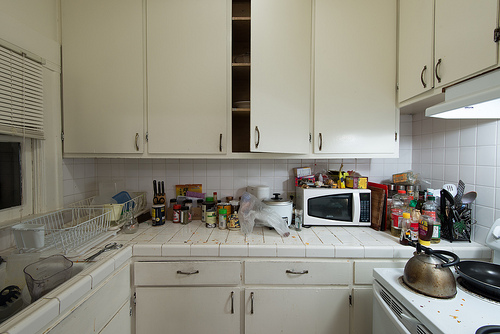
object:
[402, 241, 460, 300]
teapot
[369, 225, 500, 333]
stove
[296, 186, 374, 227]
microwave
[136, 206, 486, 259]
counter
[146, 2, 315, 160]
cabinet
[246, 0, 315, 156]
door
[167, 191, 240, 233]
jars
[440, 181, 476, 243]
utensils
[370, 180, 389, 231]
cutting board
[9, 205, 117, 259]
dish drainer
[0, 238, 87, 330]
sink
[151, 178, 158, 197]
knife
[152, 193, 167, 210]
knife block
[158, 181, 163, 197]
knife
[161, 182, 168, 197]
knife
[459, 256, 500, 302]
pan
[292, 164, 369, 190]
stuff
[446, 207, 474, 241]
caddy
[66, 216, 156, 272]
counter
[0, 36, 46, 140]
blinds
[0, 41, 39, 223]
window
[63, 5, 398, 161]
cupboards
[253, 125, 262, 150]
handles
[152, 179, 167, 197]
knives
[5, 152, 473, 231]
kitchen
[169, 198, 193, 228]
spices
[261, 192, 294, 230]
rice cooker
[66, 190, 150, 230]
dish rack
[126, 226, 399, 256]
tile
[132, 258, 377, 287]
drawer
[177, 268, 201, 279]
handle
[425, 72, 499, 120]
light